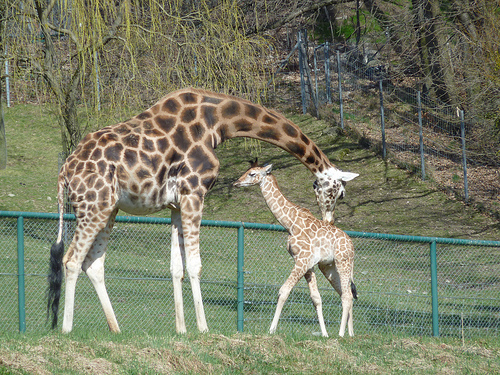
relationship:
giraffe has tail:
[0, 93, 327, 318] [18, 150, 83, 333]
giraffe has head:
[244, 155, 354, 348] [231, 152, 272, 192]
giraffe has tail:
[244, 155, 354, 348] [352, 211, 366, 317]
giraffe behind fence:
[244, 155, 354, 348] [351, 201, 498, 370]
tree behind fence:
[9, 10, 313, 183] [351, 201, 498, 370]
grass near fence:
[303, 338, 488, 374] [351, 201, 498, 370]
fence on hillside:
[310, 49, 487, 251] [297, 129, 427, 228]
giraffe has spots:
[244, 155, 354, 348] [279, 192, 337, 259]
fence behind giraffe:
[351, 201, 498, 370] [244, 155, 354, 348]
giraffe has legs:
[244, 155, 354, 348] [325, 263, 368, 345]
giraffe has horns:
[244, 155, 354, 348] [238, 147, 266, 170]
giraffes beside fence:
[0, 93, 327, 318] [351, 201, 498, 370]